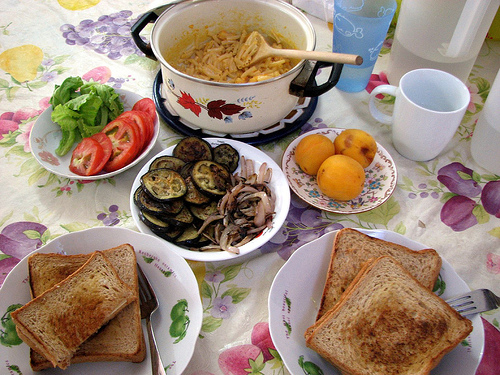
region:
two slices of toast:
[305, 226, 474, 373]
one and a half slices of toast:
[9, 241, 147, 373]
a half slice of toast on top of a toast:
[10, 242, 147, 374]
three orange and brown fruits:
[296, 128, 378, 200]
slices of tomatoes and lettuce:
[50, 75, 156, 177]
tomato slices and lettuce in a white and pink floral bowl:
[30, 76, 159, 177]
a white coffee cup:
[366, 68, 472, 163]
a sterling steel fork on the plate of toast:
[137, 262, 169, 374]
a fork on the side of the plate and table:
[442, 287, 498, 317]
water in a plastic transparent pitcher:
[390, 0, 497, 85]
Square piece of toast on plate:
[23, 280, 151, 365]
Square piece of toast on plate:
[332, 259, 445, 374]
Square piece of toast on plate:
[326, 238, 416, 347]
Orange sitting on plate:
[295, 128, 340, 178]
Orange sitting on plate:
[335, 107, 389, 171]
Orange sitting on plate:
[326, 162, 369, 202]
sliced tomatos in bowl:
[75, 106, 182, 178]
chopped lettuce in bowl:
[42, 73, 110, 148]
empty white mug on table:
[364, 42, 461, 162]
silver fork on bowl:
[424, 276, 497, 315]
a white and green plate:
[0, 227, 204, 369]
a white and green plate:
[271, 229, 485, 371]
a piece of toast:
[16, 253, 134, 365]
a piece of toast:
[306, 258, 469, 372]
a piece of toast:
[315, 220, 442, 334]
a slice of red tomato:
[65, 136, 99, 176]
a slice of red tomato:
[102, 118, 134, 169]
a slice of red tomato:
[117, 110, 153, 158]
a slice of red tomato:
[131, 98, 156, 118]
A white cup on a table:
[366, 61, 476, 166]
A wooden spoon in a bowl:
[235, 26, 372, 78]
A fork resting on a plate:
[442, 279, 498, 327]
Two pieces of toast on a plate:
[304, 220, 479, 374]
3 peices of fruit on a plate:
[283, 123, 388, 202]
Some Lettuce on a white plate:
[46, 73, 129, 154]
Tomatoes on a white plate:
[69, 94, 167, 185]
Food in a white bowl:
[124, 124, 297, 273]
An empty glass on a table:
[319, 1, 404, 101]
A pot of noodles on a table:
[127, 2, 346, 140]